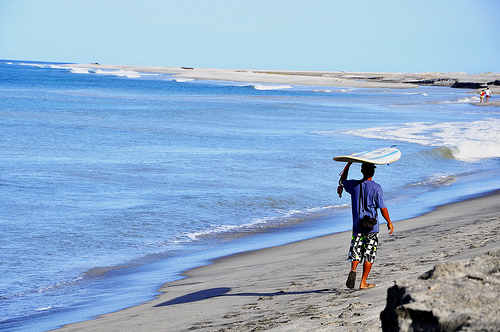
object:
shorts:
[347, 230, 380, 263]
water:
[0, 60, 500, 331]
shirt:
[344, 177, 389, 234]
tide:
[0, 156, 500, 331]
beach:
[46, 184, 500, 331]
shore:
[0, 188, 500, 331]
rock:
[378, 248, 500, 331]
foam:
[345, 117, 500, 164]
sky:
[0, 0, 500, 74]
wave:
[346, 115, 500, 162]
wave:
[219, 82, 293, 92]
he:
[338, 159, 395, 290]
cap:
[360, 160, 375, 168]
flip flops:
[357, 280, 375, 290]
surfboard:
[330, 148, 401, 166]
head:
[360, 161, 375, 178]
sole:
[344, 270, 359, 290]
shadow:
[151, 286, 342, 307]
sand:
[51, 193, 500, 331]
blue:
[247, 18, 309, 56]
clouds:
[0, 0, 500, 73]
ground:
[44, 189, 500, 331]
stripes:
[360, 148, 401, 160]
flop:
[345, 310, 364, 318]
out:
[0, 0, 500, 331]